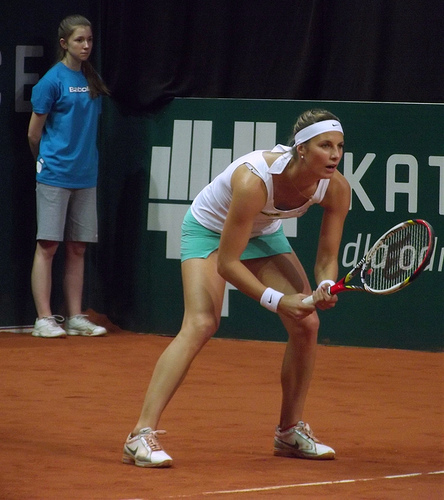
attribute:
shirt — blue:
[34, 53, 113, 187]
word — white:
[67, 82, 98, 94]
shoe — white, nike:
[120, 425, 173, 468]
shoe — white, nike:
[272, 419, 336, 458]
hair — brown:
[45, 9, 95, 59]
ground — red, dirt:
[4, 320, 442, 498]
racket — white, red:
[320, 207, 434, 311]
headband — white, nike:
[294, 117, 344, 148]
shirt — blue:
[18, 52, 106, 201]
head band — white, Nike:
[259, 98, 368, 147]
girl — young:
[26, 12, 109, 341]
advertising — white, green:
[128, 107, 442, 335]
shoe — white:
[123, 423, 169, 471]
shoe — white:
[273, 425, 336, 458]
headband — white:
[274, 118, 345, 154]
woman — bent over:
[115, 99, 362, 473]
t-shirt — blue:
[33, 71, 100, 188]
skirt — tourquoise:
[179, 207, 296, 264]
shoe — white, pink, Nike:
[128, 416, 185, 474]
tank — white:
[183, 145, 332, 244]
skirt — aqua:
[173, 205, 273, 263]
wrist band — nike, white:
[260, 287, 284, 310]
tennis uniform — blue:
[187, 220, 296, 261]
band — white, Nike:
[260, 288, 285, 308]